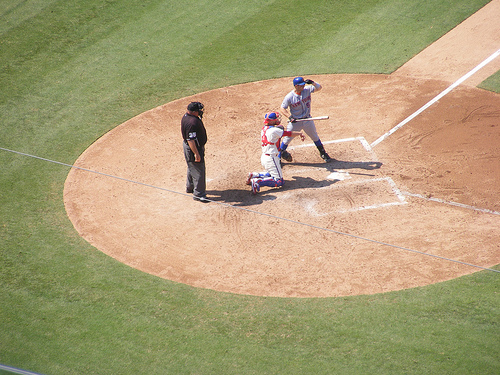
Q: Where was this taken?
A: Baseball field.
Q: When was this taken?
A: During a baseball game.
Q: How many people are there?
A: 3.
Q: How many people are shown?
A: Three.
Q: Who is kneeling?
A: The catcher.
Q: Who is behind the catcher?
A: The umpire.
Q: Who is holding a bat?
A: The batter.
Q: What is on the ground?
A: Dirt.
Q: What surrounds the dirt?
A: Grass.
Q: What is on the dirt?
A: White chalk.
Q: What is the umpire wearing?
A: A mask.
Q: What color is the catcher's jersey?
A: White.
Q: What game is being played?
A: Baseball.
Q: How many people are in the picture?
A: Three.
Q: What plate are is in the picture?
A: Home.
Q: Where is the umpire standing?
A: Behind the catcher.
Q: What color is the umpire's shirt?
A: Black.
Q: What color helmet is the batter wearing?
A: Blue.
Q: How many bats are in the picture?
A: One.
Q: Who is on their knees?
A: The catcher.